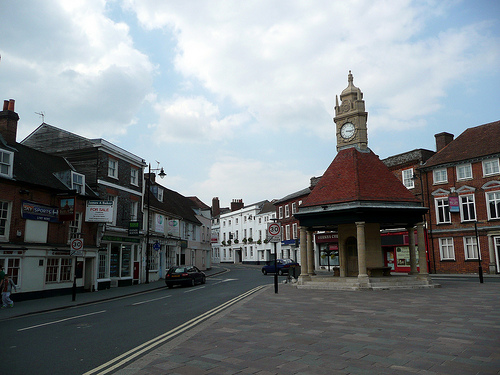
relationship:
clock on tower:
[335, 120, 360, 146] [313, 62, 387, 152]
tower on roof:
[313, 62, 387, 152] [311, 153, 408, 200]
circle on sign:
[269, 223, 280, 236] [266, 219, 290, 245]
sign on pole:
[266, 219, 290, 245] [272, 245, 288, 294]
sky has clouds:
[44, 13, 488, 126] [187, 27, 352, 80]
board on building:
[13, 223, 84, 239] [7, 114, 99, 310]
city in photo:
[50, 139, 496, 320] [36, 18, 500, 320]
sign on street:
[266, 219, 290, 245] [162, 270, 298, 338]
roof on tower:
[311, 153, 408, 200] [313, 62, 387, 152]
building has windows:
[227, 196, 278, 268] [227, 222, 274, 240]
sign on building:
[83, 196, 128, 235] [7, 114, 99, 310]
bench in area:
[369, 260, 404, 282] [302, 219, 401, 278]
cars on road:
[151, 260, 292, 280] [119, 291, 211, 334]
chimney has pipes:
[6, 111, 22, 147] [1, 94, 17, 110]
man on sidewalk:
[3, 270, 20, 314] [26, 294, 138, 312]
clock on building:
[335, 120, 360, 146] [313, 77, 424, 244]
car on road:
[159, 262, 218, 287] [119, 291, 211, 334]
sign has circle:
[266, 219, 290, 245] [269, 223, 280, 236]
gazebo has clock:
[325, 88, 390, 155] [335, 120, 360, 146]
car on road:
[256, 246, 292, 272] [119, 291, 211, 334]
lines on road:
[30, 288, 178, 317] [119, 291, 211, 334]